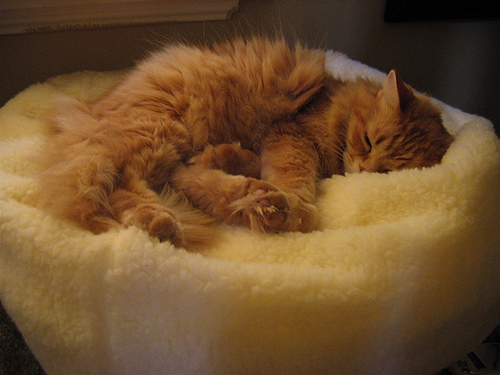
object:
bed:
[0, 43, 498, 372]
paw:
[136, 206, 179, 240]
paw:
[238, 183, 290, 227]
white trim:
[0, 0, 238, 36]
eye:
[362, 129, 374, 152]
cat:
[47, 27, 455, 246]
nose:
[357, 162, 372, 175]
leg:
[263, 127, 321, 195]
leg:
[205, 141, 262, 175]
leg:
[175, 159, 245, 213]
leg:
[112, 149, 154, 223]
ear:
[381, 69, 414, 112]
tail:
[66, 108, 170, 233]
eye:
[375, 158, 408, 172]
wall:
[1, 0, 498, 143]